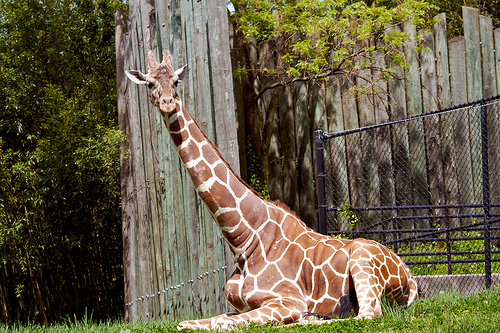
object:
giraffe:
[124, 49, 420, 331]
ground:
[4, 293, 499, 332]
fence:
[229, 5, 500, 298]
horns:
[147, 49, 172, 68]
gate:
[312, 94, 500, 296]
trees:
[0, 0, 443, 325]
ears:
[125, 63, 188, 84]